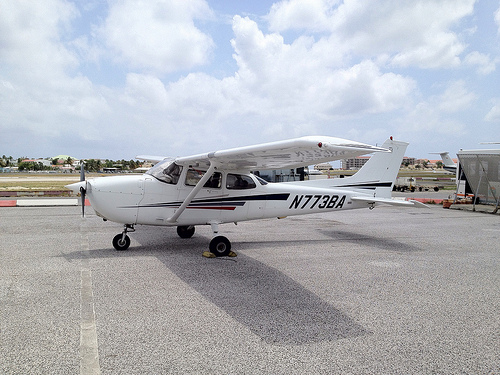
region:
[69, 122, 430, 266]
small plane on the ground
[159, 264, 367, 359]
shadow on the ground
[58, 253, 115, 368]
white line painted on the ground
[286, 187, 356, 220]
number on the plane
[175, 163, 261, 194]
windows on a plane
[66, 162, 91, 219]
propeller on a plane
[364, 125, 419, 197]
tail of a plane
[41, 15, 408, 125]
white clouds in the sky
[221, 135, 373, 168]
left wing on a plane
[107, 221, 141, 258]
front tire of a plane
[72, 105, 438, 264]
plane on the ground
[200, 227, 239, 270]
wheel of the plane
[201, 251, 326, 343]
shadow on the ground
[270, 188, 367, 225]
writing on the plane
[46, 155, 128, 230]
front of the plane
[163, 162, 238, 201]
window on side of plane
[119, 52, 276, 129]
clouds in the sky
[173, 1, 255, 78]
blue sky behind clouds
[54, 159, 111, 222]
propellor on the plane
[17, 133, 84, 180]
buildings in the background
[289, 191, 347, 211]
numbers and letters written on an airplane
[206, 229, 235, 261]
tire on the bottom of an airplane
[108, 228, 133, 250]
tire on the bottom of an airplane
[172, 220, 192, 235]
wheel on the bottom of an airplane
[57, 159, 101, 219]
propellor on the nose of an airplane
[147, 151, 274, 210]
cockpit on an airplane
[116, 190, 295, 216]
stripes on the side of an airplane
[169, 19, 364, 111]
white fluffly clouds in the sky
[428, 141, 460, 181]
tail of an airplane in the distance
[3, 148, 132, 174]
row of houses and trees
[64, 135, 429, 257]
small white personal airplane is parked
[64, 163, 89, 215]
black propeller and white nosecone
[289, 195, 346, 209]
black text indicating id number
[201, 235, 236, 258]
left rear landing wheel blocked by wooden chocks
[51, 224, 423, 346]
dark airplane shadow on the ground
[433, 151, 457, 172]
large jet tail section is visible in the distance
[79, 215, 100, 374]
dirty white painted line indicating the parking space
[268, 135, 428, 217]
long white airplane tail section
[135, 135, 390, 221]
long white wings over the door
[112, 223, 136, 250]
front landing gear is deployed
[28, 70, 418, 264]
White plane on pavement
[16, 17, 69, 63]
White clouds in the sky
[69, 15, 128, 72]
White clouds in the sky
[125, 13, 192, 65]
White clouds in the sky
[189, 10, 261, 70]
White clouds in the sky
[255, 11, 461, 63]
White clouds in the sky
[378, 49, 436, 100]
White clouds in the sky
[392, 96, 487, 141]
White clouds in the sky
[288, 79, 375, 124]
White clouds in the sky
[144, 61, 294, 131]
White clouds in the sky